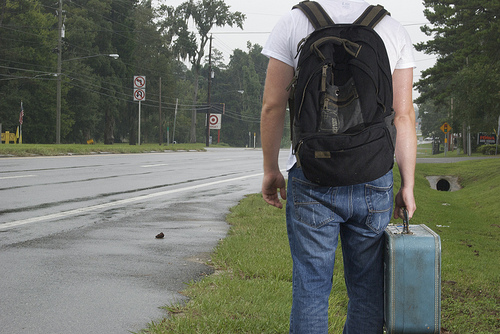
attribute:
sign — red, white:
[201, 107, 232, 146]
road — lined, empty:
[9, 131, 297, 309]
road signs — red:
[129, 73, 154, 150]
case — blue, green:
[372, 188, 448, 332]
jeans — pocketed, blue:
[258, 158, 412, 331]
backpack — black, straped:
[278, 2, 404, 192]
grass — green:
[260, 157, 500, 327]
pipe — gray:
[421, 172, 465, 191]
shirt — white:
[259, 2, 421, 95]